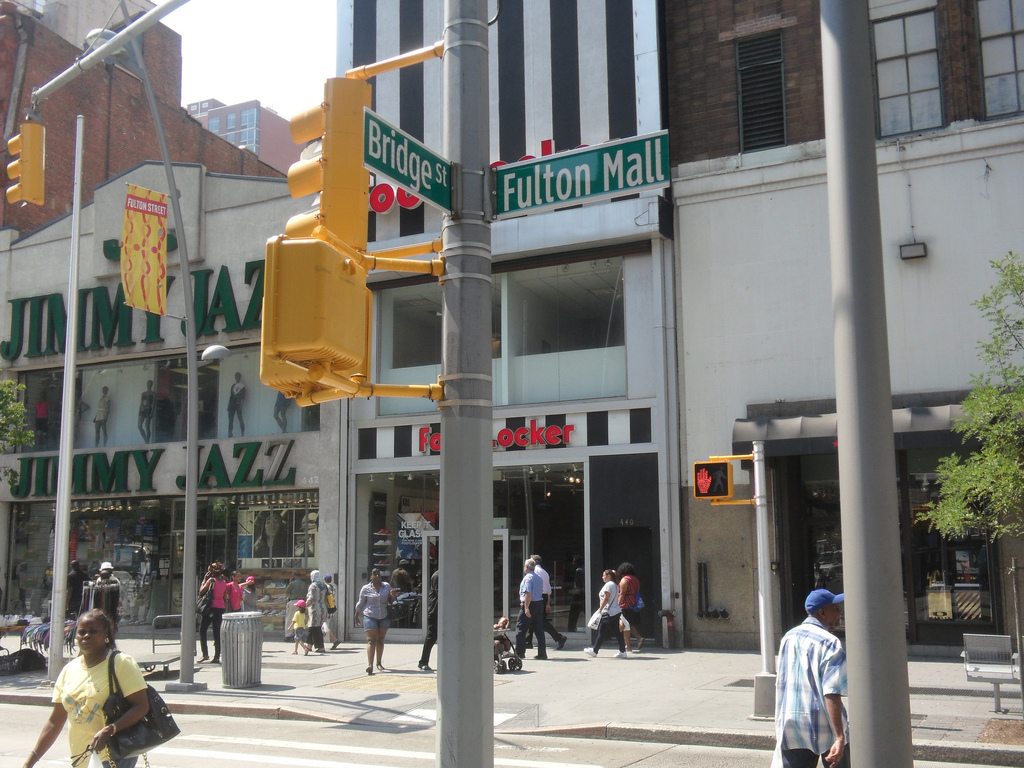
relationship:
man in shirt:
[735, 574, 854, 763] [731, 595, 894, 764]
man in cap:
[735, 574, 854, 763] [761, 559, 887, 640]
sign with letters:
[352, 384, 811, 510] [394, 405, 682, 472]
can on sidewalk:
[210, 567, 325, 764] [98, 537, 570, 723]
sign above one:
[20, 224, 368, 415] [3, 380, 371, 532]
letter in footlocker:
[379, 419, 459, 486] [392, 392, 667, 464]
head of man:
[770, 580, 863, 673] [711, 576, 856, 751]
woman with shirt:
[29, 574, 204, 763] [22, 632, 319, 754]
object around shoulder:
[89, 656, 170, 763] [83, 634, 181, 717]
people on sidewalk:
[169, 505, 731, 694] [335, 600, 698, 745]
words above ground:
[394, 405, 671, 486] [400, 613, 748, 752]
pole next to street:
[674, 412, 847, 747] [621, 658, 799, 764]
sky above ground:
[206, 23, 354, 91] [400, 613, 753, 763]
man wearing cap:
[772, 588, 852, 767] [805, 589, 848, 616]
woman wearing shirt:
[33, 554, 139, 764] [31, 630, 254, 764]